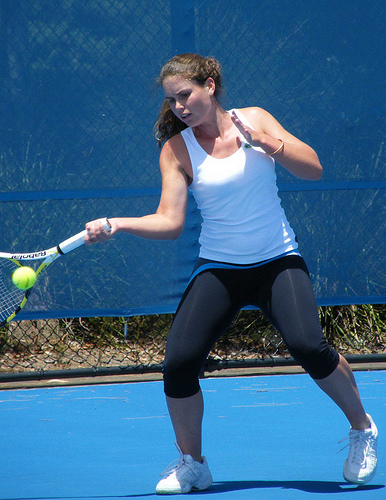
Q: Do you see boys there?
A: No, there are no boys.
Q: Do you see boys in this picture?
A: No, there are no boys.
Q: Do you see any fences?
A: Yes, there is a fence.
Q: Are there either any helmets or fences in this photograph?
A: Yes, there is a fence.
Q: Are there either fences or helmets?
A: Yes, there is a fence.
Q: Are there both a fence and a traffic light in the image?
A: No, there is a fence but no traffic lights.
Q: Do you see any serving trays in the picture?
A: No, there are no serving trays.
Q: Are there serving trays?
A: No, there are no serving trays.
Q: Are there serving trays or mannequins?
A: No, there are no serving trays or mannequins.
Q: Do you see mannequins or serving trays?
A: No, there are no serving trays or mannequins.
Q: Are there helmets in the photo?
A: No, there are no helmets.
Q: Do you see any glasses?
A: No, there are no glasses.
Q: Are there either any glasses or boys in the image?
A: No, there are no glasses or boys.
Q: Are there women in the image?
A: Yes, there is a woman.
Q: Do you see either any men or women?
A: Yes, there is a woman.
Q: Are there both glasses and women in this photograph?
A: No, there is a woman but no glasses.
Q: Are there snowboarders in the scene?
A: No, there are no snowboarders.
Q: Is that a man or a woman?
A: That is a woman.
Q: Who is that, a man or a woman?
A: That is a woman.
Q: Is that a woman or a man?
A: That is a woman.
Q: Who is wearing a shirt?
A: The woman is wearing a shirt.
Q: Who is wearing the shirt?
A: The woman is wearing a shirt.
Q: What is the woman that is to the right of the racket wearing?
A: The woman is wearing a shirt.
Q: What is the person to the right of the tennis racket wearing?
A: The woman is wearing a shirt.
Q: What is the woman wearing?
A: The woman is wearing a shirt.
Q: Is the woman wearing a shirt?
A: Yes, the woman is wearing a shirt.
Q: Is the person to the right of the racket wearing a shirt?
A: Yes, the woman is wearing a shirt.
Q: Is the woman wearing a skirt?
A: No, the woman is wearing a shirt.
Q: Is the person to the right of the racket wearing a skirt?
A: No, the woman is wearing a shirt.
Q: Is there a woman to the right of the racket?
A: Yes, there is a woman to the right of the racket.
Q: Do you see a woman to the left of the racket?
A: No, the woman is to the right of the racket.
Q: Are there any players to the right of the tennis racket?
A: No, there is a woman to the right of the tennis racket.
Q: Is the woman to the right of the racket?
A: Yes, the woman is to the right of the racket.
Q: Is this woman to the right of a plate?
A: No, the woman is to the right of the racket.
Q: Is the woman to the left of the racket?
A: No, the woman is to the right of the racket.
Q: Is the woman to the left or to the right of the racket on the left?
A: The woman is to the right of the racket.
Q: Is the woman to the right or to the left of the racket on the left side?
A: The woman is to the right of the racket.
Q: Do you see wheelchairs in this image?
A: No, there are no wheelchairs.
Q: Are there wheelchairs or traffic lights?
A: No, there are no wheelchairs or traffic lights.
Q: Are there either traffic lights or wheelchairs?
A: No, there are no wheelchairs or traffic lights.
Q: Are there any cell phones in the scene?
A: No, there are no cell phones.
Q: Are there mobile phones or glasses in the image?
A: No, there are no mobile phones or glasses.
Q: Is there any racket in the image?
A: Yes, there is a racket.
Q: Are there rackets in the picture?
A: Yes, there is a racket.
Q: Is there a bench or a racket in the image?
A: Yes, there is a racket.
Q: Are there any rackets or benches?
A: Yes, there is a racket.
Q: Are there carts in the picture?
A: No, there are no carts.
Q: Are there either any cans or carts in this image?
A: No, there are no carts or cans.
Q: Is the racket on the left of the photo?
A: Yes, the racket is on the left of the image.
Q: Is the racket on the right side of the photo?
A: No, the racket is on the left of the image.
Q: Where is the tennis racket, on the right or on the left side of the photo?
A: The tennis racket is on the left of the image.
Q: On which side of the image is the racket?
A: The racket is on the left of the image.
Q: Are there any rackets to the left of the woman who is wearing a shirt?
A: Yes, there is a racket to the left of the woman.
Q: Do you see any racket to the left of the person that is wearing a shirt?
A: Yes, there is a racket to the left of the woman.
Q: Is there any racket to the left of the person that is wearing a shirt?
A: Yes, there is a racket to the left of the woman.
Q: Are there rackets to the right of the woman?
A: No, the racket is to the left of the woman.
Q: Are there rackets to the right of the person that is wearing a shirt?
A: No, the racket is to the left of the woman.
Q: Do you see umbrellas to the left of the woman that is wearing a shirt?
A: No, there is a racket to the left of the woman.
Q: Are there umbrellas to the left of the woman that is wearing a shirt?
A: No, there is a racket to the left of the woman.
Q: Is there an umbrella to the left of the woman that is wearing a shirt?
A: No, there is a racket to the left of the woman.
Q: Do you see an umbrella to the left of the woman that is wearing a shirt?
A: No, there is a racket to the left of the woman.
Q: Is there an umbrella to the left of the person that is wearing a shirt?
A: No, there is a racket to the left of the woman.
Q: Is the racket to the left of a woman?
A: Yes, the racket is to the left of a woman.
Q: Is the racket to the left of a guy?
A: No, the racket is to the left of a woman.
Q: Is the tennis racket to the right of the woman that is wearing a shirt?
A: No, the tennis racket is to the left of the woman.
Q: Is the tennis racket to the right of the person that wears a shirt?
A: No, the tennis racket is to the left of the woman.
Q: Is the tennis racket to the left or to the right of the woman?
A: The tennis racket is to the left of the woman.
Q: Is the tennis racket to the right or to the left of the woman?
A: The tennis racket is to the left of the woman.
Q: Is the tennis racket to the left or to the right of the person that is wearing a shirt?
A: The tennis racket is to the left of the woman.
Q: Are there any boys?
A: No, there are no boys.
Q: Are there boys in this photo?
A: No, there are no boys.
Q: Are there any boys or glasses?
A: No, there are no boys or glasses.